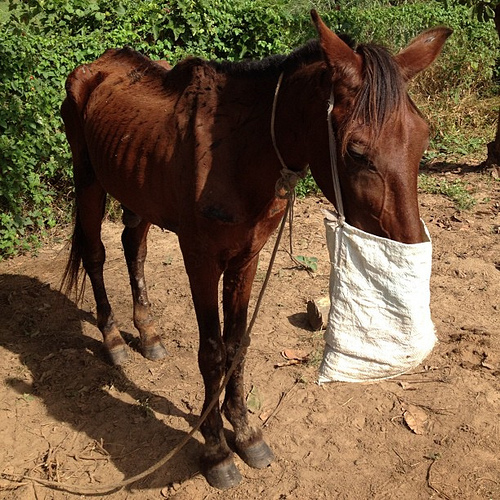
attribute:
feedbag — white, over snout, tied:
[325, 216, 440, 391]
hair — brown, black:
[357, 38, 401, 128]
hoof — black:
[142, 340, 161, 359]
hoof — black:
[109, 347, 128, 365]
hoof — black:
[242, 440, 271, 469]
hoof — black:
[208, 464, 238, 487]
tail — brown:
[59, 93, 91, 302]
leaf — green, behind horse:
[1, 5, 498, 247]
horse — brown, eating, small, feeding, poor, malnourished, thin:
[62, 10, 450, 485]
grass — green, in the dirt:
[324, 108, 493, 207]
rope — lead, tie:
[264, 50, 297, 213]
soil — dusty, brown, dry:
[12, 148, 493, 494]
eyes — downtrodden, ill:
[343, 141, 372, 167]